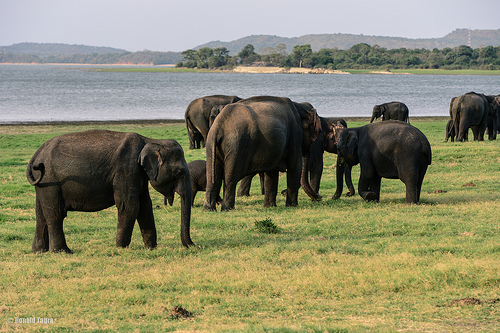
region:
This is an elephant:
[19, 115, 196, 264]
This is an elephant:
[321, 113, 442, 203]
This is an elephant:
[371, 88, 413, 133]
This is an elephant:
[191, 81, 339, 231]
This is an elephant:
[179, 81, 256, 139]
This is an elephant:
[181, 135, 232, 214]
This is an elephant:
[441, 73, 487, 154]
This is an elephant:
[446, 111, 452, 147]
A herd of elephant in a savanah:
[16, 81, 498, 265]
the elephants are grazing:
[88, 79, 493, 256]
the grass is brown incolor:
[307, 248, 442, 306]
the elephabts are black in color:
[198, 107, 441, 185]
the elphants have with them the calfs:
[156, 121, 230, 189]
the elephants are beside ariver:
[103, 73, 498, 224]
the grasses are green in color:
[444, 140, 489, 159]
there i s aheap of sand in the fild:
[168, 301, 205, 331]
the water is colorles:
[118, 59, 190, 116]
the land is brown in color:
[266, 58, 336, 78]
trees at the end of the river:
[216, 45, 322, 63]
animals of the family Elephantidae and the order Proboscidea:
[9, 18, 497, 324]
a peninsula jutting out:
[21, 25, 372, 87]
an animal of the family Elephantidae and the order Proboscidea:
[18, 127, 195, 264]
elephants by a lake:
[7, 33, 496, 261]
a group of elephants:
[17, 23, 499, 260]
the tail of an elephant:
[13, 130, 68, 199]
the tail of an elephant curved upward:
[14, 124, 78, 197]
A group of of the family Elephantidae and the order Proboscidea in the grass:
[11, 20, 441, 278]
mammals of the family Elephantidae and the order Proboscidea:
[21, 65, 498, 283]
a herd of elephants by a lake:
[11, 13, 492, 298]